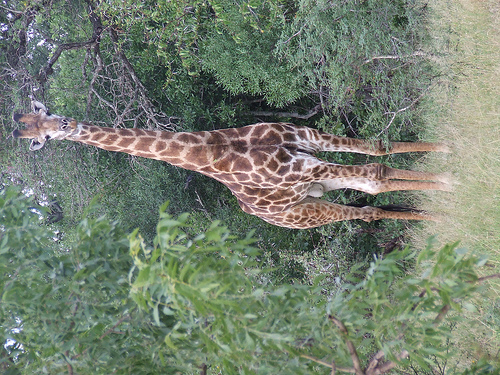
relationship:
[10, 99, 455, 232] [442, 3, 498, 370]
giraffe in field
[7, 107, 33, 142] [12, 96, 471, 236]
ossicones on head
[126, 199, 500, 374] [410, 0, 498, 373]
bush in field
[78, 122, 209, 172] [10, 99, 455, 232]
long neck on giraffe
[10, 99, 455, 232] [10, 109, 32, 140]
giraffe has horns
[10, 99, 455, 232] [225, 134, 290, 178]
giraffe has spots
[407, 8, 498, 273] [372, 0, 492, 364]
grass in field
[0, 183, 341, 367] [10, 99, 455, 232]
trees are growing behind giraffe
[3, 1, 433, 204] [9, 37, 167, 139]
tree has branches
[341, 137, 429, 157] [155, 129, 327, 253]
leg has giraffe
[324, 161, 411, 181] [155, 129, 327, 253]
leg has giraffe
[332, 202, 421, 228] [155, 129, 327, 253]
leg has giraffe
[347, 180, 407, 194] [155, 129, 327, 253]
leg has giraffe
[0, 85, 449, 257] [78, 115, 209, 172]
giraffe has long neck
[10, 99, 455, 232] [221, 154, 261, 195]
giraffe has spots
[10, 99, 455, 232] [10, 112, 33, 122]
giraffe has horn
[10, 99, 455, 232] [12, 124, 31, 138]
giraffe has horn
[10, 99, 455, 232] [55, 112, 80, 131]
giraffe has nose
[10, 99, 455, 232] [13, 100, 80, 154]
giraffe has head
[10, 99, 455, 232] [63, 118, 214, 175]
giraffe has neck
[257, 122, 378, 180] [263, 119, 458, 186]
spotted has legs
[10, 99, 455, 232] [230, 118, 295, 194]
giraffe has chest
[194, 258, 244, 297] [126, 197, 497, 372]
leaf has bush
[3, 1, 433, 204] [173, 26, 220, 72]
tree has leaf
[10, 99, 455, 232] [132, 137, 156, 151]
giraffe has spot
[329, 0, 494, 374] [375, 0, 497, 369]
field has grass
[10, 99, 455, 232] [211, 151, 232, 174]
giraffe has spot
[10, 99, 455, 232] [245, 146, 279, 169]
giraffe has spot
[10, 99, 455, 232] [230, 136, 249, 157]
giraffe has spot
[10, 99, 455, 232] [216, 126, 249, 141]
giraffe has spot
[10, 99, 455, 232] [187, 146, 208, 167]
giraffe has spot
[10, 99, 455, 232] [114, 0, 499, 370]
giraffe standing among plants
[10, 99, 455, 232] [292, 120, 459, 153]
giraffe has leg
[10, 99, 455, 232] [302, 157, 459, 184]
giraffe has leg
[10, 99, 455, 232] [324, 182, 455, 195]
giraffe has leg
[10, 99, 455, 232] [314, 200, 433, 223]
giraffe has leg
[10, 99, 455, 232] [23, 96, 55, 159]
giraffe has ears